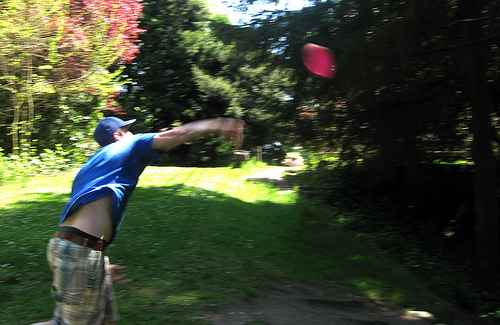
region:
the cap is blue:
[79, 91, 138, 133]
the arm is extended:
[135, 104, 262, 158]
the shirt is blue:
[64, 142, 149, 198]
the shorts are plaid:
[32, 246, 115, 313]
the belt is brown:
[41, 230, 106, 251]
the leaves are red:
[63, 9, 140, 42]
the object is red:
[294, 32, 335, 92]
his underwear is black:
[57, 226, 83, 234]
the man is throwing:
[30, 94, 270, 324]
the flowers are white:
[149, 218, 208, 273]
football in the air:
[285, 32, 351, 87]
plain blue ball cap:
[86, 100, 141, 143]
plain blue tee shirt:
[51, 130, 172, 247]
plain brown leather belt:
[45, 223, 122, 258]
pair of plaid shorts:
[31, 227, 120, 323]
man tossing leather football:
[32, 32, 361, 324]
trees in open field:
[1, 0, 64, 205]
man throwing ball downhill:
[17, 22, 436, 323]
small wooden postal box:
[221, 140, 253, 175]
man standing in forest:
[1, 0, 271, 323]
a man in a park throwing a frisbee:
[0, 0, 493, 313]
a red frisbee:
[295, 32, 341, 87]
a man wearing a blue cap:
[2, 102, 242, 317]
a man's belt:
[41, 225, 111, 256]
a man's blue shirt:
[47, 130, 177, 255]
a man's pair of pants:
[36, 217, 128, 319]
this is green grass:
[170, 185, 310, 265]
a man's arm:
[136, 112, 276, 185]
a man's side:
[80, 206, 110, 243]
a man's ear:
[104, 129, 125, 145]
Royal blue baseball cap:
[89, 115, 144, 142]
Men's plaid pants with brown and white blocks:
[44, 209, 116, 322]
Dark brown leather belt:
[45, 217, 135, 264]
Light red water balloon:
[302, 42, 346, 86]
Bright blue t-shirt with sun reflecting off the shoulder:
[45, 121, 171, 214]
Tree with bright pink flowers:
[54, 3, 169, 84]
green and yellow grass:
[128, 140, 342, 277]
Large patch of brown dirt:
[192, 268, 449, 323]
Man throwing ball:
[46, 114, 298, 314]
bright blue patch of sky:
[209, 1, 351, 78]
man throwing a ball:
[46, 62, 278, 323]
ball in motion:
[286, 28, 337, 85]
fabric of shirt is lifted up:
[55, 175, 137, 257]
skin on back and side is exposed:
[60, 187, 125, 246]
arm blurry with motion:
[144, 102, 262, 163]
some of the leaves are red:
[85, 0, 152, 62]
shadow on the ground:
[7, 195, 372, 320]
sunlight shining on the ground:
[211, 174, 280, 199]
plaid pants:
[32, 235, 123, 324]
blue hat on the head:
[84, 106, 136, 142]